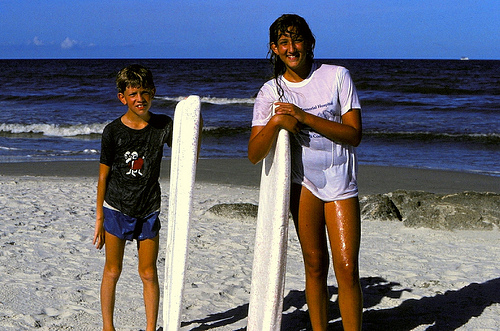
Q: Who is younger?
A: The boy.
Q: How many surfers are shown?
A: Two.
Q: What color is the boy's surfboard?
A: White.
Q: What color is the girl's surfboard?
A: White.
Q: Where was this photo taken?
A: The beach.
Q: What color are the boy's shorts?
A: Blue.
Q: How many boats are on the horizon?
A: One.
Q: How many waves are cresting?
A: Two.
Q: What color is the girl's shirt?
A: White.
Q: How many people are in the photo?
A: Two.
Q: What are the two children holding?
A: Surfboards.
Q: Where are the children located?
A: Beach.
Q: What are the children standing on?
A: Sand.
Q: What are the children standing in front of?
A: Ocean.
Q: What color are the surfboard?
A: White.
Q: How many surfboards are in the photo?
A: Two.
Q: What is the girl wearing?
A: T-shirt and swimsuit.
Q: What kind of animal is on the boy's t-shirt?
A: Bird.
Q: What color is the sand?
A: Light tan.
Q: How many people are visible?
A: Two.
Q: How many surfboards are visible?
A: Two.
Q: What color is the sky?
A: Blue.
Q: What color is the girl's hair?
A: Brown.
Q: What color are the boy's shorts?
A: Blue.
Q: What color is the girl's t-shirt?
A: White.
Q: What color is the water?
A: Blue.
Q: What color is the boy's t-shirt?
A: Black.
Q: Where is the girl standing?
A: To the right of the boy.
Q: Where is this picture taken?
A: A beach.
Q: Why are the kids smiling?
A: Because they're having fun.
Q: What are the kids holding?
A: Surfboards.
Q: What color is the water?
A: Blue.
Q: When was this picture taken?
A: Daytime.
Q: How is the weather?
A: Sunny.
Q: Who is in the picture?
A: A girl and boy.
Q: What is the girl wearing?
A: A white tee shirt.